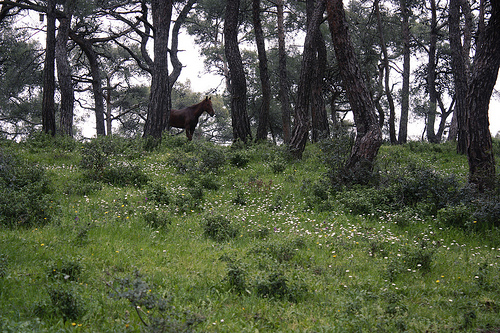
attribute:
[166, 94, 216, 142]
horse — big, brown, looking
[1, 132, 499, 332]
grass — green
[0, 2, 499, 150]
sky — grey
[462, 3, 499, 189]
trunk — curved, crooked, curving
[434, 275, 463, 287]
flowers — yellow, small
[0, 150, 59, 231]
bush — green, large